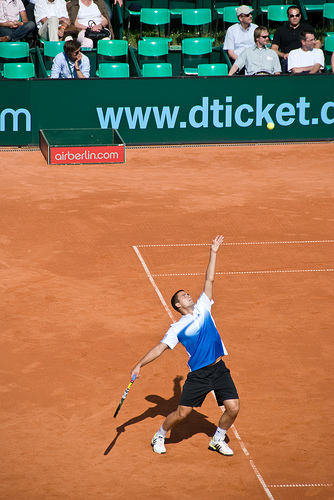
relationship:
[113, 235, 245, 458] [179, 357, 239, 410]
man wearing shorts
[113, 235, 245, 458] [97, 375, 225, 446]
man has shadow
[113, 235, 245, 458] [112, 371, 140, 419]
man has racket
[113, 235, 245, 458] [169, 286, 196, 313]
man has head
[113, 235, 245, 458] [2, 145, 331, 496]
man on court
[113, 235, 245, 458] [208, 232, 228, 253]
man has hand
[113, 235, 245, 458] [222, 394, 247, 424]
man has knee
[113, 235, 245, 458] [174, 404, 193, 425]
man has knee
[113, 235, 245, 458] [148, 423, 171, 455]
man has shoe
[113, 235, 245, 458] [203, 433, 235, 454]
man has shoe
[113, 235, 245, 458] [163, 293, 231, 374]
man wearing shirt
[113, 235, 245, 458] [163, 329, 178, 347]
man has biciep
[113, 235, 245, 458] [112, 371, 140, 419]
man holding racket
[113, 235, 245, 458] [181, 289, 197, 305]
man has face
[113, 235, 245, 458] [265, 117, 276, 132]
man trying to hit ball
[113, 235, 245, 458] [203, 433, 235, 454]
man wearing shoe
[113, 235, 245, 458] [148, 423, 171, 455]
man wearing shoe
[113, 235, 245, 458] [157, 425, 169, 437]
man wearing sock